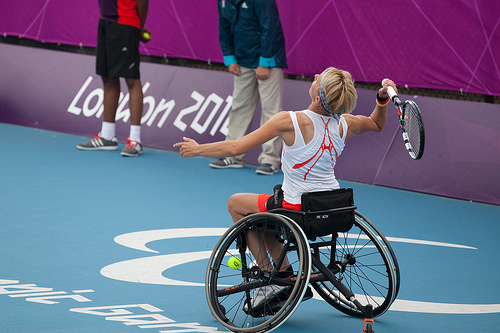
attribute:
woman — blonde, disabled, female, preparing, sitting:
[189, 65, 398, 284]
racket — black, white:
[383, 77, 431, 163]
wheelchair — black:
[205, 193, 401, 331]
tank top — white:
[282, 108, 347, 205]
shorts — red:
[259, 183, 313, 222]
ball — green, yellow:
[228, 255, 242, 271]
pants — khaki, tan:
[219, 66, 296, 167]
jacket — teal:
[214, 1, 294, 67]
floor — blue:
[3, 120, 500, 332]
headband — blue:
[315, 69, 339, 114]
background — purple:
[2, 1, 500, 203]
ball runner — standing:
[69, 1, 153, 162]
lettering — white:
[0, 211, 498, 331]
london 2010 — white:
[67, 72, 260, 155]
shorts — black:
[91, 17, 147, 80]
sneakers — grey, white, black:
[70, 132, 143, 158]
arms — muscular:
[175, 80, 396, 158]